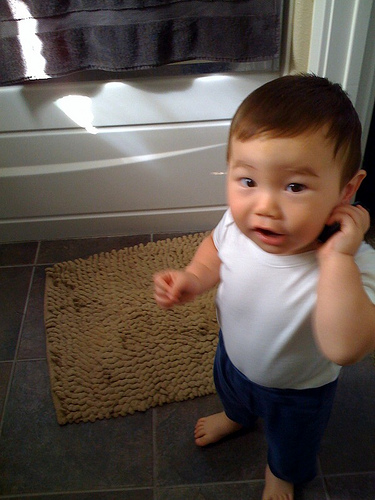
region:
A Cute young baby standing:
[219, 100, 348, 493]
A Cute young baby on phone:
[194, 72, 352, 446]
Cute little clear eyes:
[240, 177, 309, 201]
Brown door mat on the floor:
[51, 256, 147, 424]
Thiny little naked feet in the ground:
[187, 413, 286, 493]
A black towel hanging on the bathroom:
[4, 0, 290, 79]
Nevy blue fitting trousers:
[205, 338, 340, 483]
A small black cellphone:
[311, 195, 372, 240]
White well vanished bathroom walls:
[38, 111, 192, 230]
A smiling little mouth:
[244, 211, 286, 247]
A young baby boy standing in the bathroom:
[151, 77, 373, 435]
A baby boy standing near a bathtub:
[139, 52, 361, 494]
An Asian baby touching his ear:
[154, 69, 349, 388]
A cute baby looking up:
[137, 67, 362, 497]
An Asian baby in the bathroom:
[121, 63, 373, 483]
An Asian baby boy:
[140, 67, 373, 490]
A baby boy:
[166, 78, 373, 428]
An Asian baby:
[144, 86, 331, 403]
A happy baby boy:
[141, 85, 372, 418]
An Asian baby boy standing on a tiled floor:
[144, 71, 373, 452]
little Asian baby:
[146, 63, 373, 497]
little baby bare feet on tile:
[191, 410, 256, 450]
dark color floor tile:
[0, 421, 171, 486]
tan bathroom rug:
[41, 252, 173, 429]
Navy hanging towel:
[3, 1, 300, 78]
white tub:
[6, 81, 141, 239]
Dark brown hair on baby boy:
[225, 68, 365, 164]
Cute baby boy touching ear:
[150, 62, 372, 498]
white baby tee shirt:
[210, 211, 374, 387]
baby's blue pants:
[205, 328, 346, 487]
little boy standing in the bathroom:
[151, 88, 372, 499]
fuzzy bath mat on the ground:
[41, 224, 242, 443]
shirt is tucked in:
[216, 347, 325, 419]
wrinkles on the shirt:
[278, 272, 320, 349]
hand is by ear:
[327, 162, 372, 262]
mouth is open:
[250, 222, 284, 248]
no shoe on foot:
[190, 396, 243, 449]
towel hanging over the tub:
[3, 0, 292, 89]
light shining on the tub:
[62, 93, 113, 139]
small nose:
[246, 197, 280, 226]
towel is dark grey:
[0, 8, 290, 70]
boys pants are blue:
[216, 383, 315, 467]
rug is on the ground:
[49, 292, 207, 414]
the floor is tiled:
[16, 420, 196, 493]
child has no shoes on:
[191, 419, 229, 441]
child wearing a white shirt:
[223, 259, 323, 387]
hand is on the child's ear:
[332, 169, 365, 271]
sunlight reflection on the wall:
[47, 87, 150, 154]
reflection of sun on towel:
[10, 5, 57, 89]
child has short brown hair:
[252, 75, 346, 147]